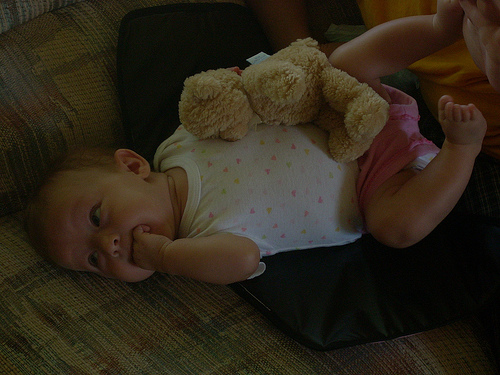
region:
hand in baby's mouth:
[128, 217, 156, 270]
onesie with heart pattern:
[149, 102, 374, 287]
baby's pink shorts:
[326, 67, 438, 209]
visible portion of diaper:
[404, 145, 439, 173]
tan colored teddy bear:
[178, 40, 392, 168]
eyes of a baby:
[79, 200, 110, 277]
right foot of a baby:
[432, 87, 484, 159]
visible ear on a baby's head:
[103, 138, 156, 187]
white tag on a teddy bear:
[245, 49, 271, 71]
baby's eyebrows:
[65, 191, 85, 276]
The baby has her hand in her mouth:
[68, 197, 242, 322]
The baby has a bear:
[158, 56, 400, 198]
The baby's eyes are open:
[29, 143, 204, 339]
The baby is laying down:
[24, 77, 481, 317]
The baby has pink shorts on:
[299, 60, 489, 224]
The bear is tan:
[197, 60, 364, 155]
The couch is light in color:
[30, 292, 192, 365]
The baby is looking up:
[44, 182, 139, 305]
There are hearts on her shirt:
[221, 158, 351, 275]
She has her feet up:
[346, 15, 498, 172]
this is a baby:
[45, 52, 445, 272]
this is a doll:
[185, 47, 376, 157]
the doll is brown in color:
[213, 86, 293, 101]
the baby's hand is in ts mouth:
[121, 213, 266, 286]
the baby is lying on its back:
[22, 25, 455, 285]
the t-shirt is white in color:
[233, 150, 331, 205]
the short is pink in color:
[393, 117, 411, 137]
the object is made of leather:
[286, 275, 377, 303]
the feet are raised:
[387, 2, 479, 207]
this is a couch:
[16, 30, 94, 109]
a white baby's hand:
[133, 227, 260, 294]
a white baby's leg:
[362, 85, 489, 248]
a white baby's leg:
[333, 4, 479, 73]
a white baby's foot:
[435, 84, 492, 156]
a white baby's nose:
[101, 229, 125, 257]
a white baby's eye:
[82, 245, 103, 270]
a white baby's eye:
[85, 198, 109, 233]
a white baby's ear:
[116, 140, 154, 182]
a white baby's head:
[21, 140, 181, 296]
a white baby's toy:
[179, 43, 384, 161]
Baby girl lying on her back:
[24, 66, 489, 300]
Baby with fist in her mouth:
[21, 150, 220, 301]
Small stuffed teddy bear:
[166, 38, 381, 157]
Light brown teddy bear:
[167, 41, 381, 156]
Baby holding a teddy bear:
[15, 57, 381, 292]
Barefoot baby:
[405, 0, 493, 196]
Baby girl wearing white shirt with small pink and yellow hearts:
[45, 122, 302, 288]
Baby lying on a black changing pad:
[88, 2, 493, 320]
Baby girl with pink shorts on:
[21, 82, 436, 245]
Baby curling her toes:
[421, 76, 493, 186]